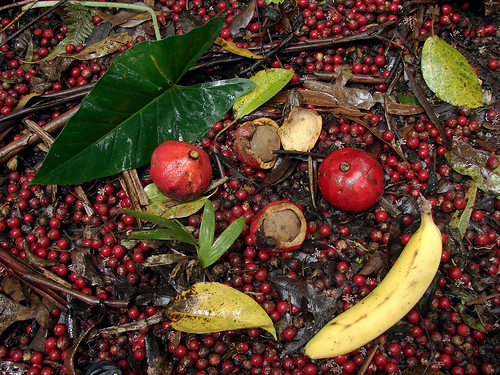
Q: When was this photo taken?
A: During the day.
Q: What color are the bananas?
A: Yellow.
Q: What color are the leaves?
A: Green.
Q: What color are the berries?
A: Red.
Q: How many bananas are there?
A: One.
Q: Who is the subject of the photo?
A: The fruit.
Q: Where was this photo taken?
A: Above the ground.